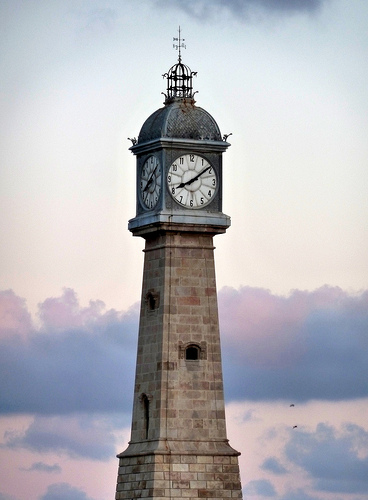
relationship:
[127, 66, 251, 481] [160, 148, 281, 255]
tower with clock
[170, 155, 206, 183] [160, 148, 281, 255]
numerals on clock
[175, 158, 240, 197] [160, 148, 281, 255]
hand on clock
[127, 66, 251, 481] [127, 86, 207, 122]
tower has roof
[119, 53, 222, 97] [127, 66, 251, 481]
ornament on tower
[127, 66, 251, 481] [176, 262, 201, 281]
tower has brick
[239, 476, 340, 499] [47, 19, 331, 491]
person took photo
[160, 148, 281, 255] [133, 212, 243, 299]
clock has base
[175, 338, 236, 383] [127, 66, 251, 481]
window on tower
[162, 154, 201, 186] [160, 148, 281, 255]
face on clock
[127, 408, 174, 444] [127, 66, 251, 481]
archway on tower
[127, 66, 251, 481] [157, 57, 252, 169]
tower has bell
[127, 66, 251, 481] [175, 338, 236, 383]
tower has window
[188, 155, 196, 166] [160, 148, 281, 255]
numerals on clock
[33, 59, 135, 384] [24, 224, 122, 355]
clouds in sky